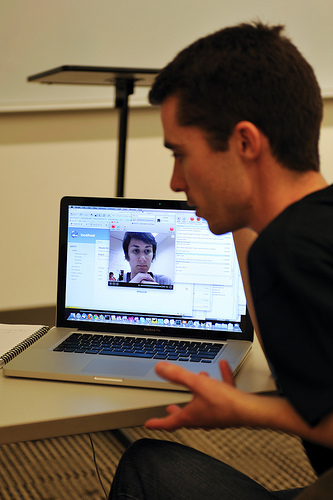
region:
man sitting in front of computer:
[67, 24, 308, 298]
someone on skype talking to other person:
[78, 185, 285, 336]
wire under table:
[67, 407, 145, 487]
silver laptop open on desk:
[53, 185, 267, 389]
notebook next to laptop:
[1, 286, 61, 366]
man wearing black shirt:
[184, 173, 331, 434]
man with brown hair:
[77, 38, 277, 242]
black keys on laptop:
[58, 312, 252, 382]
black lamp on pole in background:
[33, 40, 181, 198]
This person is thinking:
[107, 230, 176, 287]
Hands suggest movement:
[129, 348, 264, 440]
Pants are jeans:
[111, 434, 242, 498]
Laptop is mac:
[3, 186, 263, 410]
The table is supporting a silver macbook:
[0, 319, 329, 429]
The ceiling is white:
[13, 11, 329, 133]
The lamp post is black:
[29, 46, 173, 214]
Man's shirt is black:
[197, 214, 313, 423]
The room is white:
[3, 112, 152, 199]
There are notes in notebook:
[0, 319, 61, 370]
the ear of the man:
[231, 120, 263, 162]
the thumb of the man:
[153, 359, 206, 395]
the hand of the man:
[143, 355, 239, 441]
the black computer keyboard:
[49, 326, 227, 366]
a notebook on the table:
[0, 316, 51, 364]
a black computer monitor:
[53, 192, 256, 345]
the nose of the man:
[164, 156, 189, 197]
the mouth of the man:
[183, 197, 204, 220]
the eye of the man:
[169, 141, 189, 168]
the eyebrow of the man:
[161, 136, 186, 151]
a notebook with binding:
[0, 318, 48, 370]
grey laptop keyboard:
[20, 326, 252, 408]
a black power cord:
[78, 435, 116, 498]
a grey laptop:
[3, 198, 258, 402]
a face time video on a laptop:
[108, 230, 175, 288]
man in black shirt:
[136, 42, 331, 432]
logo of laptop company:
[138, 324, 165, 333]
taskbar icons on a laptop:
[64, 309, 243, 338]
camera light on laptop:
[147, 191, 175, 215]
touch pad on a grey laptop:
[80, 354, 158, 383]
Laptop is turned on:
[5, 188, 268, 406]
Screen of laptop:
[58, 198, 248, 331]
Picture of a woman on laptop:
[94, 219, 184, 299]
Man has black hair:
[90, 15, 332, 499]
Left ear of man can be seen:
[228, 113, 267, 162]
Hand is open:
[140, 350, 299, 456]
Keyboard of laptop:
[52, 330, 234, 370]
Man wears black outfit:
[87, 12, 331, 499]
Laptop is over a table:
[0, 193, 281, 453]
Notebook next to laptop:
[2, 319, 50, 381]